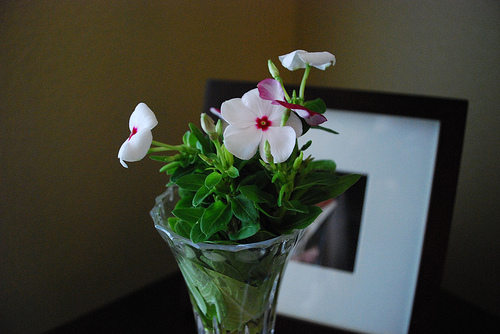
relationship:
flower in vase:
[105, 40, 338, 210] [144, 183, 333, 333]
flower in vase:
[113, 100, 202, 184] [144, 183, 333, 333]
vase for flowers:
[144, 183, 333, 333] [109, 45, 359, 212]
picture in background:
[313, 75, 466, 333] [11, 4, 500, 84]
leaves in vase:
[196, 202, 232, 241] [144, 183, 333, 333]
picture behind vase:
[313, 75, 466, 333] [144, 183, 333, 333]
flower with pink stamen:
[214, 84, 303, 165] [253, 116, 272, 133]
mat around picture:
[368, 110, 427, 334] [299, 166, 372, 275]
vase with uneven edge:
[144, 183, 333, 333] [161, 230, 304, 254]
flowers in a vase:
[109, 45, 359, 212] [144, 183, 333, 333]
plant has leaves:
[105, 40, 338, 210] [167, 161, 270, 233]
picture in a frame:
[299, 166, 372, 275] [313, 75, 466, 333]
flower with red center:
[214, 84, 303, 165] [253, 116, 272, 133]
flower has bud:
[214, 84, 303, 165] [196, 109, 220, 139]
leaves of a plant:
[167, 161, 270, 233] [105, 40, 338, 210]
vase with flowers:
[144, 183, 333, 333] [109, 45, 359, 212]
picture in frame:
[313, 75, 466, 333] [198, 76, 472, 332]